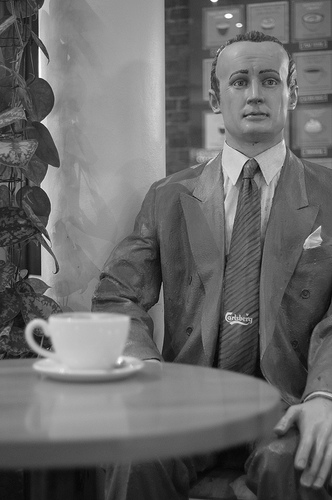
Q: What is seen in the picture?
A: A cafe'.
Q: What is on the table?
A: A cup.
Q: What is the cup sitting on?
A: A saucer.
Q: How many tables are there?
A: One.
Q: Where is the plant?
A: Next to the table.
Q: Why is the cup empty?
A: It's pretend coffee.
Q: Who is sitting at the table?
A: A mannequin.